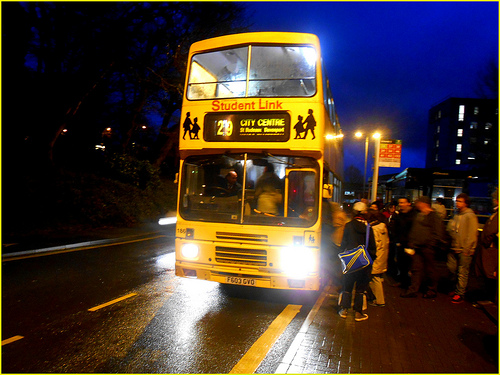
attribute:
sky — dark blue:
[17, 2, 499, 188]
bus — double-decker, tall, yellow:
[165, 27, 344, 316]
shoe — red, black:
[439, 286, 475, 307]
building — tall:
[423, 97, 499, 187]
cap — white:
[352, 202, 366, 209]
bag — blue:
[335, 245, 370, 275]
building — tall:
[424, 96, 497, 222]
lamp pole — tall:
[353, 130, 383, 195]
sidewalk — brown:
[286, 252, 498, 373]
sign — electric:
[201, 107, 291, 142]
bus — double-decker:
[176, 30, 345, 292]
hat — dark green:
[408, 191, 431, 206]